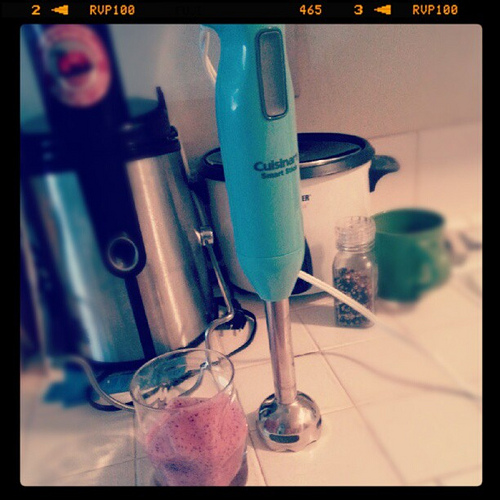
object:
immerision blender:
[196, 24, 326, 455]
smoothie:
[127, 348, 248, 488]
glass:
[131, 345, 253, 488]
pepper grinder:
[330, 209, 382, 331]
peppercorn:
[344, 275, 352, 283]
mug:
[372, 207, 455, 304]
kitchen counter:
[21, 214, 483, 488]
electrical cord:
[299, 268, 482, 408]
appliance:
[198, 131, 401, 298]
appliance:
[18, 16, 237, 375]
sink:
[418, 219, 482, 309]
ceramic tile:
[310, 406, 468, 487]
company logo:
[250, 154, 300, 173]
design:
[29, 23, 131, 109]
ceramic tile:
[320, 342, 472, 413]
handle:
[368, 153, 401, 193]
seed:
[189, 417, 197, 425]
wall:
[21, 25, 482, 220]